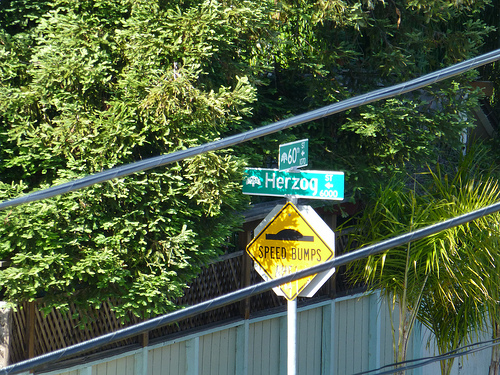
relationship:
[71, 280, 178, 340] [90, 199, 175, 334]
fence under tree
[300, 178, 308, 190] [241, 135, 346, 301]
letter in sign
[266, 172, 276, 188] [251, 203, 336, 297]
letter in sign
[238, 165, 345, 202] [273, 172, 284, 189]
green signs in letter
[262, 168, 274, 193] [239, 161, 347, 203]
letter in sign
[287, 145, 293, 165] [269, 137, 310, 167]
white number in sign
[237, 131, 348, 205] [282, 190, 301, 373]
green signs in pole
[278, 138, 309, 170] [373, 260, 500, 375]
sign in fence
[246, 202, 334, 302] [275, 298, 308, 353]
diamond sign on post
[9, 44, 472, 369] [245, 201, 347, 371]
wires below sign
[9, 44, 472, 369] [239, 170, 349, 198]
wires below sign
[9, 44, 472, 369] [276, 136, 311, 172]
wires below sign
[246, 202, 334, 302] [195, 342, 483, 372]
diamond sign by side of road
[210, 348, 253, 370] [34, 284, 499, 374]
part of a wall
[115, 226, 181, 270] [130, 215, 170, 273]
part of a branch